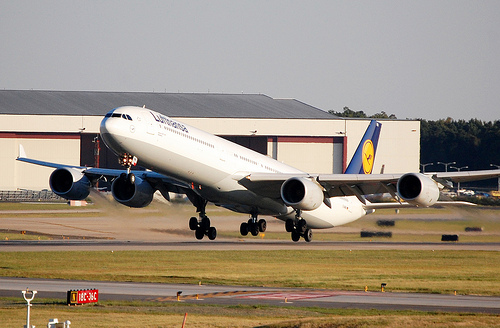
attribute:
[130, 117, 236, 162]
airplane — white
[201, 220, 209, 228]
wheel — black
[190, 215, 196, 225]
wheel — black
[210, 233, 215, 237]
wheel — black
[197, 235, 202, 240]
wheel — black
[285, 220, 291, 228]
wheel — black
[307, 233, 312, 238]
wheel — black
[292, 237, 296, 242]
wheel — black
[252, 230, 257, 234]
wheel — black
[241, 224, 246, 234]
wheel — black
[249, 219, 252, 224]
wheel — black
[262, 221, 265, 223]
wheel — black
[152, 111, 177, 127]
writing — blue